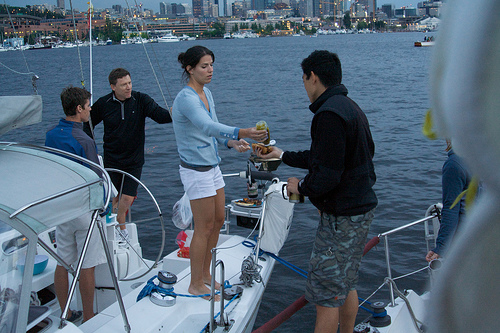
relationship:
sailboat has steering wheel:
[0, 84, 308, 331] [90, 163, 168, 287]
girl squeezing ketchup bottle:
[159, 42, 265, 302] [253, 119, 271, 149]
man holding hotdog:
[276, 39, 402, 329] [244, 142, 274, 156]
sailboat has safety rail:
[250, 0, 483, 329] [253, 200, 453, 330]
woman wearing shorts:
[160, 30, 275, 300] [175, 159, 227, 205]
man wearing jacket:
[32, 79, 114, 329] [40, 116, 108, 218]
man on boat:
[32, 79, 114, 329] [1, 16, 302, 329]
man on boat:
[77, 59, 172, 248] [1, 16, 302, 329]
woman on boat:
[160, 30, 275, 300] [1, 16, 302, 329]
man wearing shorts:
[77, 59, 172, 248] [100, 152, 150, 196]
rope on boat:
[231, 241, 392, 331] [273, 188, 483, 330]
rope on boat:
[123, 269, 243, 302] [1, 16, 302, 329]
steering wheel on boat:
[99, 167, 168, 288] [1, 16, 302, 329]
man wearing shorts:
[276, 39, 402, 329] [302, 207, 376, 308]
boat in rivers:
[1, 16, 302, 329] [15, 48, 447, 220]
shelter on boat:
[0, 118, 133, 304] [1, 16, 302, 329]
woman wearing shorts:
[160, 30, 275, 300] [171, 159, 224, 209]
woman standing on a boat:
[160, 30, 275, 300] [1, 16, 302, 329]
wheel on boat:
[77, 155, 197, 300] [1, 16, 302, 329]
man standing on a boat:
[77, 59, 172, 248] [1, 16, 302, 329]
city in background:
[16, 7, 405, 40] [6, 3, 446, 73]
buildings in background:
[3, 2, 437, 40] [0, 3, 443, 51]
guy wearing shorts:
[263, 36, 396, 327] [303, 189, 388, 324]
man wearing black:
[77, 59, 172, 248] [89, 91, 176, 177]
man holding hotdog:
[276, 39, 402, 329] [249, 123, 287, 163]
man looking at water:
[32, 79, 114, 329] [25, 38, 476, 258]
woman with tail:
[160, 30, 275, 300] [169, 47, 189, 70]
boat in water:
[409, 32, 452, 57] [25, 38, 476, 258]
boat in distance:
[409, 32, 452, 57] [377, 20, 456, 141]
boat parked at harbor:
[1, 16, 302, 329] [5, 192, 481, 330]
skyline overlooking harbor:
[6, 2, 481, 52] [27, 13, 457, 48]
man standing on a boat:
[77, 59, 172, 248] [5, 74, 359, 331]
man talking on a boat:
[77, 59, 172, 248] [1, 16, 302, 329]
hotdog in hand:
[245, 119, 287, 159] [238, 119, 313, 209]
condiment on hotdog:
[253, 111, 279, 141] [245, 136, 288, 163]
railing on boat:
[238, 199, 462, 330] [249, 172, 478, 329]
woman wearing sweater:
[160, 30, 275, 300] [168, 87, 238, 165]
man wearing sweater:
[276, 39, 402, 329] [283, 84, 381, 213]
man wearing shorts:
[32, 79, 114, 329] [53, 211, 105, 267]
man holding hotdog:
[276, 39, 402, 329] [252, 149, 282, 161]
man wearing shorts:
[77, 59, 172, 248] [84, 67, 173, 225]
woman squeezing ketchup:
[160, 30, 275, 300] [253, 124, 269, 144]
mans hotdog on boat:
[237, 53, 363, 212] [1, 16, 302, 329]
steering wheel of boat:
[99, 167, 168, 288] [1, 16, 302, 329]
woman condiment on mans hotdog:
[160, 30, 275, 300] [237, 53, 363, 212]